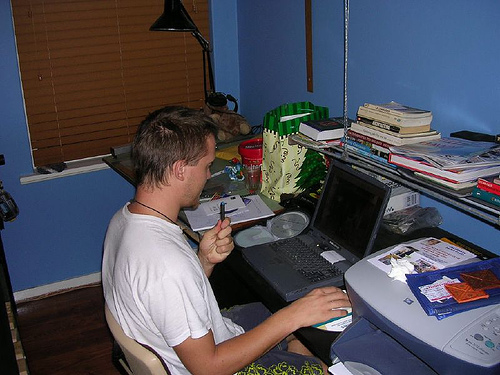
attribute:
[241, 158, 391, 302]
laptop — black, gre ad black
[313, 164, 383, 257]
screen — off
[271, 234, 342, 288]
keyboard — grey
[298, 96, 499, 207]
books — arranged, stacked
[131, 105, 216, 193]
hair — short, brow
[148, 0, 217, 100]
lamp — black, metal, off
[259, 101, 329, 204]
bag — green, yellow, brown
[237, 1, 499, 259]
wall — blue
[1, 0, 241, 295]
wall — blue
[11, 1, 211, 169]
blinds — brown, horizontal, vertical, dark brow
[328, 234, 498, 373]
printer — gray, blue, gre ad blue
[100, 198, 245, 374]
shirt — white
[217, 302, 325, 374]
shorts — gray, green, gre ad lime, gree ad ellow